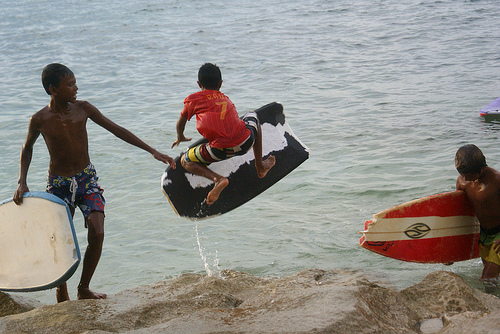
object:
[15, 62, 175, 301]
kids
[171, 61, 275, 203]
kids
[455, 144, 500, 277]
kids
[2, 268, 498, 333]
beach